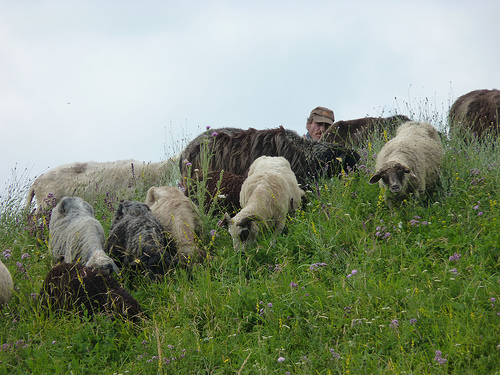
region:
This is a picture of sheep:
[54, 118, 330, 293]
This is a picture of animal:
[209, 117, 364, 207]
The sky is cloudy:
[51, 33, 187, 132]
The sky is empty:
[123, 72, 168, 129]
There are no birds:
[76, 82, 201, 134]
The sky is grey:
[59, 39, 109, 90]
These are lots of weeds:
[306, 222, 382, 327]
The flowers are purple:
[266, 282, 306, 307]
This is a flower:
[432, 346, 458, 373]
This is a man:
[272, 93, 327, 156]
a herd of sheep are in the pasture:
[5, 89, 497, 371]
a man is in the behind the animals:
[293, 103, 338, 145]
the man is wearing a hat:
[306, 104, 333, 130]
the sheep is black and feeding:
[25, 254, 164, 349]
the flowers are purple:
[303, 260, 327, 272]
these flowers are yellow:
[309, 219, 320, 240]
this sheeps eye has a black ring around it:
[234, 229, 257, 247]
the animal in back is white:
[20, 159, 185, 201]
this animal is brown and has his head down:
[177, 124, 348, 189]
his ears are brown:
[398, 161, 417, 178]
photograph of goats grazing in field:
[23, 20, 484, 351]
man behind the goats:
[280, 90, 350, 150]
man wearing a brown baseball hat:
[291, 100, 341, 150]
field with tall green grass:
[25, 112, 481, 363]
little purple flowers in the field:
[415, 241, 466, 363]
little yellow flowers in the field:
[125, 245, 145, 275]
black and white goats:
[12, 66, 487, 328]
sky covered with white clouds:
[45, 16, 442, 102]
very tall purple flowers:
[193, 118, 222, 211]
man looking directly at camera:
[296, 100, 336, 159]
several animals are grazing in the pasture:
[8, 67, 484, 328]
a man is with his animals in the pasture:
[308, 98, 340, 148]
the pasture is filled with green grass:
[151, 203, 496, 365]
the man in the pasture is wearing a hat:
[308, 103, 336, 130]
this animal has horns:
[213, 206, 269, 232]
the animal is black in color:
[26, 258, 152, 328]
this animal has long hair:
[172, 127, 344, 169]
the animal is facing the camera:
[365, 158, 417, 201]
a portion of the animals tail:
[18, 182, 45, 219]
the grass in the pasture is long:
[240, 107, 435, 300]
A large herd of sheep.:
[11, 16, 443, 303]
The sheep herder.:
[185, 55, 495, 256]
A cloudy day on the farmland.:
[15, 78, 497, 371]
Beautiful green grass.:
[305, 226, 495, 371]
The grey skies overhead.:
[1, 5, 231, 120]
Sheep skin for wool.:
[15, 116, 301, 326]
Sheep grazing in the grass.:
[30, 123, 305, 309]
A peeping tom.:
[165, 62, 490, 228]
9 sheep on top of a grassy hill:
[0, 76, 496, 372]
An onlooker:
[357, 117, 458, 229]